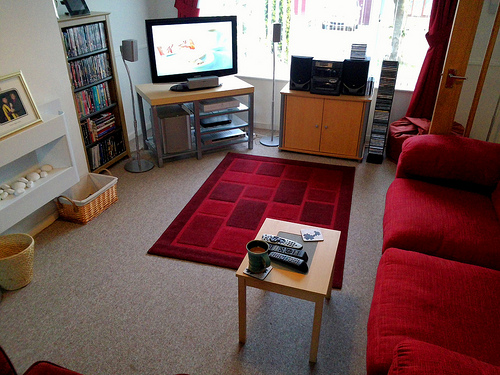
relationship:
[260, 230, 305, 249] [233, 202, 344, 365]
remote on table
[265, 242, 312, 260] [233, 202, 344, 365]
remote on table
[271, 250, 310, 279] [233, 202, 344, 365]
remote on table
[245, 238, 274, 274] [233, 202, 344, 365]
coffee on table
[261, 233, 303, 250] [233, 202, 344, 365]
remote are on table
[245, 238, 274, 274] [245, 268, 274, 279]
coffee on a coaster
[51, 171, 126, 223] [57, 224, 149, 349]
basket on floor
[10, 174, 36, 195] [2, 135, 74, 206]
rocks are on shelf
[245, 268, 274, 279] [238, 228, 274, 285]
coaster beneath mug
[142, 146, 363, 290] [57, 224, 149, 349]
rug on floor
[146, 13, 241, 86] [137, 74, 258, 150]
television on stand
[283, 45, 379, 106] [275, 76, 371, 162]
stereo on cabinet